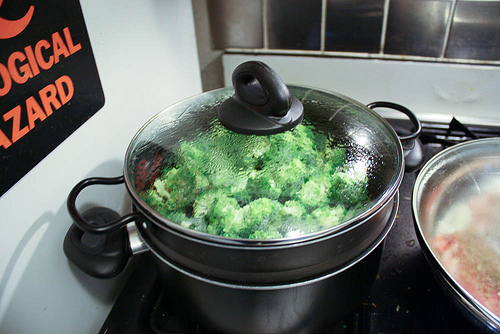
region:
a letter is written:
[52, 75, 74, 103]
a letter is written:
[30, 80, 60, 117]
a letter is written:
[0, 105, 32, 134]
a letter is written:
[61, 21, 84, 52]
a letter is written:
[31, 35, 61, 67]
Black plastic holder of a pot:
[200, 49, 319, 138]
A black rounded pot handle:
[57, 168, 149, 239]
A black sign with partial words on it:
[2, 4, 109, 189]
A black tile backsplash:
[239, 5, 496, 62]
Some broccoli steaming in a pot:
[222, 166, 329, 221]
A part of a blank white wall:
[123, 14, 190, 96]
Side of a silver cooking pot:
[232, 258, 366, 322]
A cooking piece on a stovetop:
[415, 138, 498, 332]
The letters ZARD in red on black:
[0, 78, 83, 143]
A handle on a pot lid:
[58, 172, 133, 232]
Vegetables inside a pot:
[153, 125, 358, 218]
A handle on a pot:
[372, 99, 418, 143]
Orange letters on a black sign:
[2, 8, 82, 153]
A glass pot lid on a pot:
[123, 85, 404, 238]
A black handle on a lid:
[60, 208, 127, 271]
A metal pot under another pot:
[125, 196, 411, 332]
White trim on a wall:
[232, 48, 495, 119]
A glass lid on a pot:
[415, 131, 499, 329]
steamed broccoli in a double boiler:
[122, 78, 404, 249]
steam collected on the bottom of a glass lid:
[127, 80, 396, 229]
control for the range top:
[433, 110, 478, 146]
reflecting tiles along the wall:
[212, 0, 499, 56]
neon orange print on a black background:
[1, 1, 106, 201]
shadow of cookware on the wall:
[1, 154, 165, 330]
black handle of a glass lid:
[216, 48, 301, 139]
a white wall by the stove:
[2, 4, 211, 331]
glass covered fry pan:
[408, 128, 496, 327]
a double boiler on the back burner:
[61, 57, 423, 332]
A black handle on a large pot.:
[230, 59, 291, 116]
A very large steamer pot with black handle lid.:
[65, 59, 423, 332]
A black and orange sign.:
[0, 3, 105, 194]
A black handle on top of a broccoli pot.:
[228, 60, 290, 117]